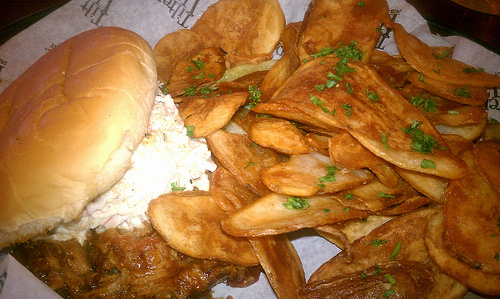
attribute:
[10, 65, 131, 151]
hamburger bun — bread, at chinese store, plain, brown, white, tan, white topped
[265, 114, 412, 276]
potato slices — on plate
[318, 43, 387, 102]
green season — parsley, piled, herb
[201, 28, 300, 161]
fries — potatos, sliced potatos, piled, large, abundant, brown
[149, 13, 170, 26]
wrap paper — white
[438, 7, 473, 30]
background — dark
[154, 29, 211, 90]
cheese — melted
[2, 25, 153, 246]
bun — brown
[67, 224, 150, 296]
hamburger — at chinese restauran, very large, unhealthy, meat, brown, tan